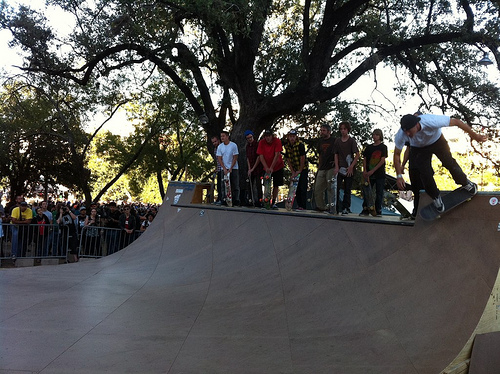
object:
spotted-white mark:
[176, 207, 182, 214]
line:
[81, 282, 152, 324]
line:
[176, 264, 226, 330]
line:
[264, 225, 298, 319]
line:
[335, 225, 378, 290]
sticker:
[174, 186, 184, 195]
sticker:
[171, 192, 182, 204]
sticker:
[199, 210, 205, 217]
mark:
[487, 193, 494, 222]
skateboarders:
[210, 113, 488, 221]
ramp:
[63, 233, 465, 350]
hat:
[400, 114, 419, 128]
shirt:
[395, 114, 449, 148]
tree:
[7, 1, 483, 216]